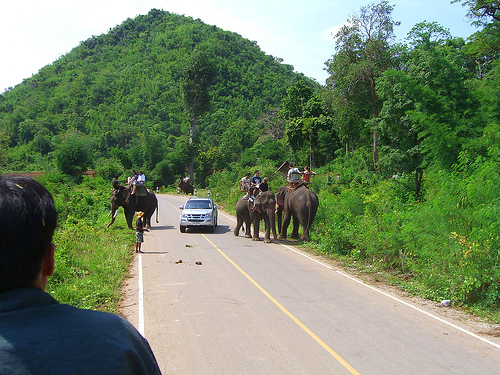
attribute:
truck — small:
[177, 196, 219, 232]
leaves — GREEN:
[89, 72, 118, 102]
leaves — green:
[68, 138, 85, 166]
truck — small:
[176, 194, 221, 236]